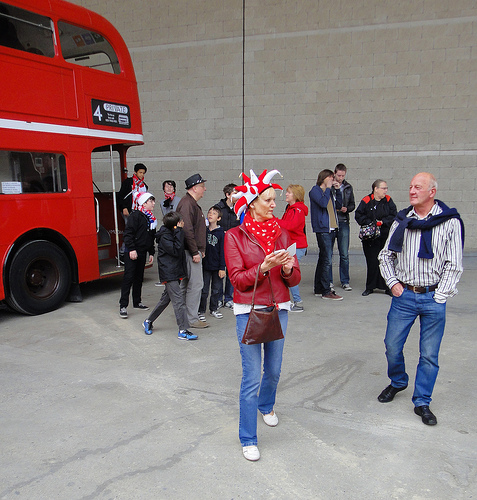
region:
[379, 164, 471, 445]
a man in jeans with a sweater tied around his neck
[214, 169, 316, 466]
a lady with a jester hat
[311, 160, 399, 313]
three people waiting in the background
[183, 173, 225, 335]
a kid looking to his grandpa for direction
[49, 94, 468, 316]
a crowd of people leaving a bus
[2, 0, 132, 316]
a red bus that just dropped off some people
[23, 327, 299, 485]
concrete floor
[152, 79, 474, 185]
drab looking stone gray wall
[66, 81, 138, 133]
bus signage to designate bus number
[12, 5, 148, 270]
double decker bus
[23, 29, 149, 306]
red double decker bus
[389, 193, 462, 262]
blue sweater with tied sleeves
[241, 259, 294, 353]
purse hanging from arm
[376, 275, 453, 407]
blue jeans with belt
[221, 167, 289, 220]
red and white hat on woman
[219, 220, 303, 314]
red leather jacket on woman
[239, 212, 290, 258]
red and white scarf on neck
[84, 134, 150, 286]
open door way of bus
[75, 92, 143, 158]
sign over bus door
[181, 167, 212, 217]
man in black hat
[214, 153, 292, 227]
red and white hat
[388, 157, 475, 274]
man in striped shirt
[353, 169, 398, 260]
red on dark jacket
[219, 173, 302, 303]
lady wearing red coat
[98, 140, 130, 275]
metal railing on bus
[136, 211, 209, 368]
boy wearing blue shoes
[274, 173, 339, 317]
lady wearing red sweatshirt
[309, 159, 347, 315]
guy with brown scarf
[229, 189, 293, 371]
lady carrying brown purse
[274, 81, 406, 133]
gray tiles on wall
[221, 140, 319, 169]
deep lines in the wall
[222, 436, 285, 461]
white sneakers on woman's foot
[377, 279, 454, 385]
man wearing blue jeans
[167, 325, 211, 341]
blue and black sneakers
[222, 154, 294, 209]
clown looking white and red hat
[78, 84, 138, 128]
number on side of bus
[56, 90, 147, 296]
large red passenger bus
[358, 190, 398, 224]
red and black jacket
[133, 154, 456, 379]
people standing on the sidewalk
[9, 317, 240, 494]
Concret floor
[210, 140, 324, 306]
A woman in red and white hat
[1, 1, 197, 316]
Red double decker bus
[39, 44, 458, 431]
Passenger stepping out of the bus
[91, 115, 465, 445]
Tourist making sight seeing plans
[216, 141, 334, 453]
A woman in red leather jacket and scarf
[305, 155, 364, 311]
Two men in discussion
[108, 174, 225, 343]
A family with two kids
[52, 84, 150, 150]
Route 4 sign on the bus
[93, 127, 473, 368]
People in spring or fall clothing